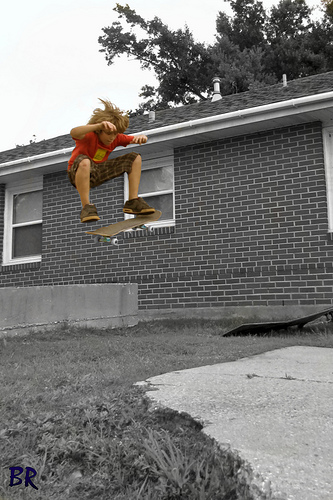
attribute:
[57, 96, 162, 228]
boy — jumping, small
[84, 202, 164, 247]
skateboard — brown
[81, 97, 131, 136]
hair — flying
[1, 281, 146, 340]
wall — stone, cement, concrete, miniature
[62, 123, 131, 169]
shirt — red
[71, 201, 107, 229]
shoe — brown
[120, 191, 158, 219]
shoe — brown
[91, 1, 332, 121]
tree — looming, large